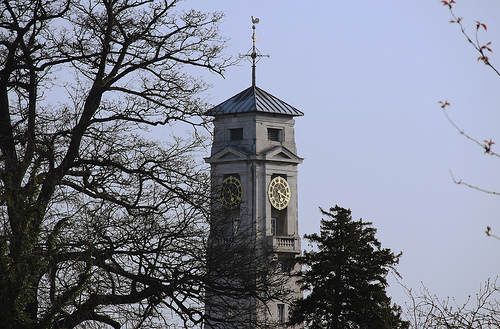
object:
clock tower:
[197, 11, 308, 325]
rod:
[235, 13, 273, 84]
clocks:
[220, 175, 244, 210]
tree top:
[293, 204, 402, 283]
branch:
[440, 99, 478, 145]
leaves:
[484, 140, 490, 144]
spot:
[235, 87, 253, 101]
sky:
[0, 0, 500, 327]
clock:
[267, 176, 291, 210]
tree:
[0, 0, 237, 325]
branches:
[137, 118, 170, 127]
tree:
[297, 204, 407, 328]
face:
[270, 178, 290, 207]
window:
[229, 126, 244, 141]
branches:
[201, 10, 223, 26]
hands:
[278, 191, 291, 200]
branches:
[161, 0, 174, 12]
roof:
[203, 86, 305, 113]